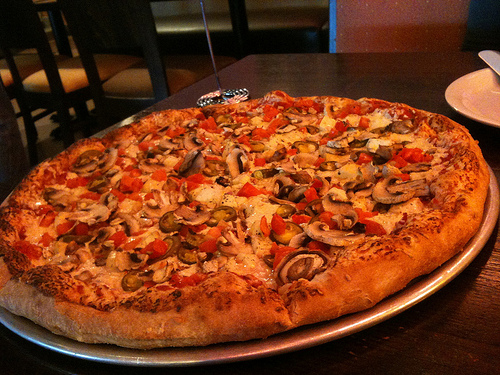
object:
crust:
[0, 269, 291, 350]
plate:
[442, 66, 499, 130]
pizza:
[0, 90, 490, 350]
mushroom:
[273, 249, 332, 287]